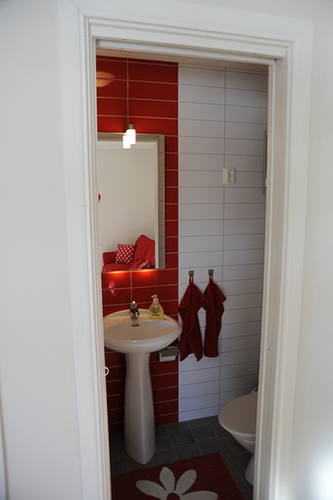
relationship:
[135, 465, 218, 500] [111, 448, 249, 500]
flower on carpet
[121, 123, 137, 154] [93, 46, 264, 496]
light in bathroom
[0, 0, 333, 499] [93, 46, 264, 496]
bathroom in bathroom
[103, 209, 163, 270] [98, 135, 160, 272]
reflection in mirror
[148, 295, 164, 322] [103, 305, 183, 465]
hand soap on pedestal sink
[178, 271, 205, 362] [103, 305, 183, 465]
towel beside pedestal sink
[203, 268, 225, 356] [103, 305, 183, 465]
towel beside pedestal sink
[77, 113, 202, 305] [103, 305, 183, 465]
mirror above pedestal sink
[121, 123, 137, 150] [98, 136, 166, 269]
light above mirror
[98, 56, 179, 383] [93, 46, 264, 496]
red wall in bathroom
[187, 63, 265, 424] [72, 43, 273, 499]
white wall in bathroom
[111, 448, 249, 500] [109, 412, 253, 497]
carpet on floor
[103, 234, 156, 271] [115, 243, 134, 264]
red couch with a pillow